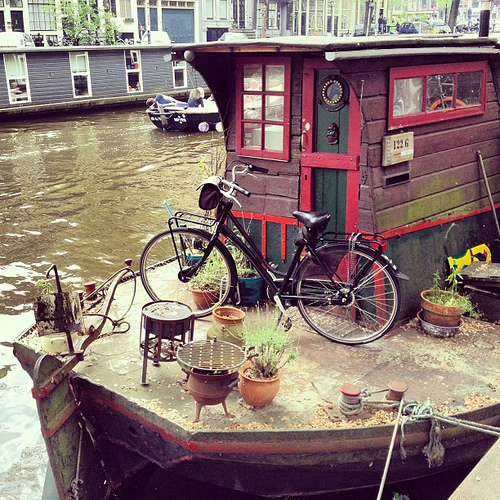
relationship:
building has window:
[180, 30, 481, 324] [230, 93, 295, 164]